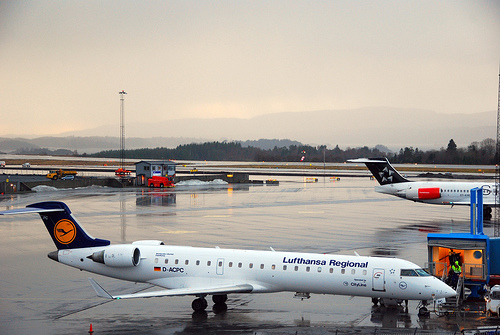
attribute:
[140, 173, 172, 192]
car — red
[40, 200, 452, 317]
plane — white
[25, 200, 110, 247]
tail — gold, blue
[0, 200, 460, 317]
white plane — parked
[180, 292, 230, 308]
tires — under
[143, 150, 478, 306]
cone — orange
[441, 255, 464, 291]
person — airport traffic controller